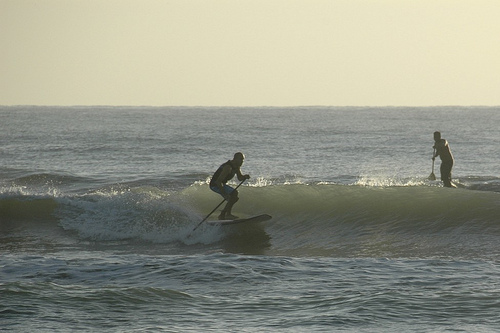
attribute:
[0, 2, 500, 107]
sky — early morning color, yellow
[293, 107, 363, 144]
water — calm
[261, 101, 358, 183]
water — dark blue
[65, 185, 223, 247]
trail — splash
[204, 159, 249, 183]
jacket — black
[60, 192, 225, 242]
wake — small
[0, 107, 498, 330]
water — murky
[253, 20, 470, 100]
sky — white, yellow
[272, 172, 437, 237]
water — splashing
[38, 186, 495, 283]
wave front — rough, advancing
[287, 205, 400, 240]
water — murky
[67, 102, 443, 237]
wave — green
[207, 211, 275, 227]
board — white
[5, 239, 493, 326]
water — gentle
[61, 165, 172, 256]
wave — white